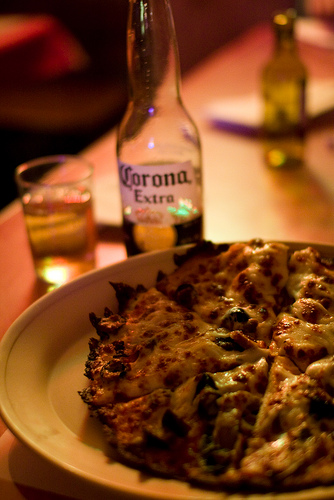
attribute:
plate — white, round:
[0, 240, 333, 499]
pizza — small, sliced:
[77, 241, 333, 490]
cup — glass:
[15, 154, 97, 287]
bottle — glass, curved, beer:
[115, 1, 205, 260]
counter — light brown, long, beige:
[0, 2, 332, 497]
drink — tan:
[21, 187, 94, 287]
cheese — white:
[95, 247, 333, 480]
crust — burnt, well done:
[77, 282, 154, 408]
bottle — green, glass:
[259, 9, 308, 172]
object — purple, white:
[208, 77, 333, 141]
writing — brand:
[117, 164, 192, 203]